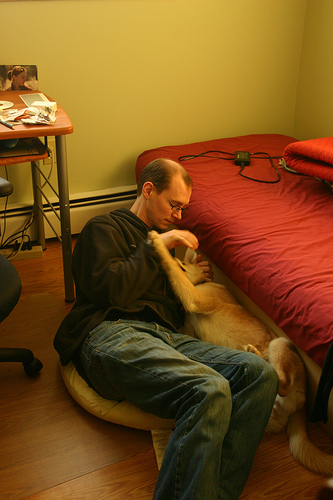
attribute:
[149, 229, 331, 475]
dog — large, brown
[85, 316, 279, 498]
jeans — BLUE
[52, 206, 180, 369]
shirt — BLACK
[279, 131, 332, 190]
blanket —  red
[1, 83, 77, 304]
desk —  messy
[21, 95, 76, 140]
paper — crumpled